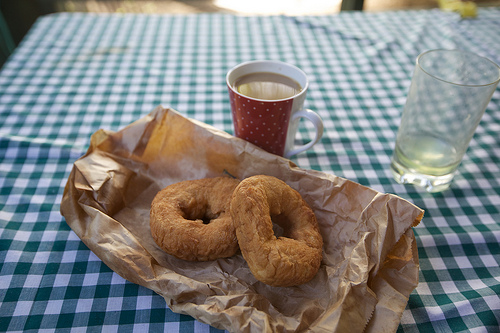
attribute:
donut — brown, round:
[229, 173, 325, 288]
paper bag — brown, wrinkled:
[58, 104, 425, 332]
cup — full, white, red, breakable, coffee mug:
[225, 59, 325, 160]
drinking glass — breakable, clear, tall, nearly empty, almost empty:
[388, 48, 500, 193]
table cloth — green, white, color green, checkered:
[0, 5, 499, 331]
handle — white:
[286, 108, 324, 159]